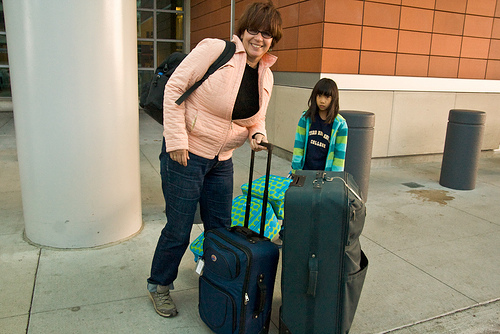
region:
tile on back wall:
[358, 52, 392, 70]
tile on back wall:
[362, 28, 399, 52]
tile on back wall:
[325, 25, 358, 48]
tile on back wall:
[397, 52, 425, 72]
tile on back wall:
[428, 57, 453, 74]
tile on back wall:
[400, 12, 429, 29]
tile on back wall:
[363, 0, 394, 29]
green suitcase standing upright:
[288, 175, 360, 327]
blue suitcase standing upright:
[198, 226, 269, 322]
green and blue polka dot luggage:
[190, 165, 298, 267]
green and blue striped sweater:
[288, 110, 353, 182]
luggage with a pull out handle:
[200, 137, 277, 332]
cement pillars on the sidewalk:
[435, 101, 491, 201]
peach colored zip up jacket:
[146, 35, 277, 175]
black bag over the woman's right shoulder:
[139, 37, 239, 119]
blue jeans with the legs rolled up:
[141, 138, 238, 323]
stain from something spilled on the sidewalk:
[406, 182, 460, 217]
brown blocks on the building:
[321, 0, 492, 77]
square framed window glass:
[136, 3, 183, 58]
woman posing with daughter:
[185, 5, 379, 332]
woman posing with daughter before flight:
[147, 0, 403, 308]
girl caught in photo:
[290, 57, 371, 195]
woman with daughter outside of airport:
[148, 1, 419, 308]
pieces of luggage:
[191, 175, 406, 322]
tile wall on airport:
[336, 9, 481, 62]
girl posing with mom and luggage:
[241, 0, 421, 317]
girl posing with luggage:
[233, 72, 362, 259]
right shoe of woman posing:
[118, 250, 200, 325]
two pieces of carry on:
[208, 175, 378, 308]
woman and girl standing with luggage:
[139, 0, 397, 316]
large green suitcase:
[273, 155, 390, 332]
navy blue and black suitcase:
[190, 213, 296, 326]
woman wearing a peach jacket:
[166, 0, 290, 188]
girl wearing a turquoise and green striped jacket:
[284, 71, 362, 177]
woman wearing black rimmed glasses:
[203, 6, 293, 102]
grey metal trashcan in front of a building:
[419, 80, 487, 211]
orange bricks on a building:
[326, 5, 493, 70]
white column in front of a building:
[5, 7, 133, 275]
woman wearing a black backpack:
[115, 6, 295, 139]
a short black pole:
[438, 100, 490, 190]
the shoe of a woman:
[146, 276, 180, 318]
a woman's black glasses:
[243, 23, 275, 41]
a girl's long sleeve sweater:
[294, 110, 348, 177]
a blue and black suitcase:
[197, 135, 292, 332]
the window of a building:
[152, 10, 190, 37]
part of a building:
[320, 0, 498, 77]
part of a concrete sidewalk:
[346, 155, 498, 332]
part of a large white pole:
[2, 0, 147, 248]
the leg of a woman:
[146, 138, 198, 283]